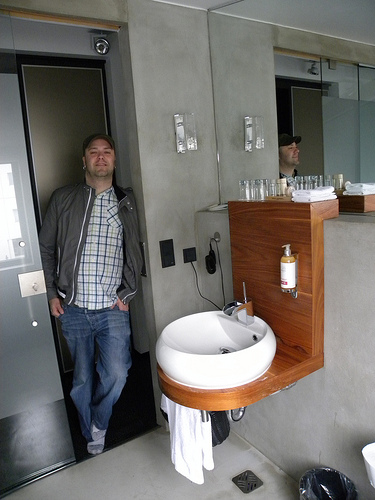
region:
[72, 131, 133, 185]
Man with earrings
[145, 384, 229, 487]
white towel hanging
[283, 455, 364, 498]
Black trash can with bag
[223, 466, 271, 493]
Dark grey drain on floor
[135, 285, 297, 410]
Big white bowl like sink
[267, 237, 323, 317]
Hand soap with white label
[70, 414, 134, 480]
White and grey socks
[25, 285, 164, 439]
Blue jeans with phone in pocket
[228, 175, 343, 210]
Numerous glass cups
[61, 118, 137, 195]
Man with green cap on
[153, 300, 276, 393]
A round white sink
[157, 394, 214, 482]
A white towel underneath the sink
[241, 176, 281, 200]
Empty glass jars on a wooden counter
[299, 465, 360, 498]
A black trash can with plastic inside it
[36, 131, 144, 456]
Man smiling leaning against the doorway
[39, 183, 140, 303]
Man wearing a gray jacket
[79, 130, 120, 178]
Man wearing a black hat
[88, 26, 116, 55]
A round light above the doorway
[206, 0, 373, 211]
Man reflecting in the bathroom mirror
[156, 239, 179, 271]
A black light switch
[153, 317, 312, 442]
this is a sink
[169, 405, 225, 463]
a towel to dry handfs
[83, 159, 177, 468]
a guy is standing on the door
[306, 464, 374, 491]
a black bin is seen on the iomage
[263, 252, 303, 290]
detergent for washing hands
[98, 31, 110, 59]
a camera is on the back ground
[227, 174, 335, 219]
glasses are on the image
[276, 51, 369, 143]
this is a mirror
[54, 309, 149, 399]
he has won jeans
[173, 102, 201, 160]
a glass on the wall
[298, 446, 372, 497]
black trash can with plastic liner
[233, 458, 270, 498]
Drain in the floor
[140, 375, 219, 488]
White hand towel hanging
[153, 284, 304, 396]
White round sink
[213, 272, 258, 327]
silver metal faucet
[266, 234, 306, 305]
Hand soap on the wall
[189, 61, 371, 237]
Mirror on a wall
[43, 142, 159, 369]
Man in a plaid shirt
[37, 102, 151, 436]
Man standing wearing a hat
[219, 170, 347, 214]
Empty glasses on a shelf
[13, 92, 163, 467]
man leaning in doorway in bathroom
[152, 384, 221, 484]
white towel hanging from below the sink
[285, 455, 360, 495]
black garbage can lined with a plastic bag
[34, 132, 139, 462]
man wearing plaid shirt with jacket and jeans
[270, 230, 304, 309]
soap dispenser hanging above sink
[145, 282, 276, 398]
round sink with deep bowl on extended wooden support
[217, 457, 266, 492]
drain in floor under the sink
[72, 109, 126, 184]
man with narrow eyes smiling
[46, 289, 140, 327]
fingertips in jean pockets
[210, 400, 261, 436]
curved drainage pipe under the sink